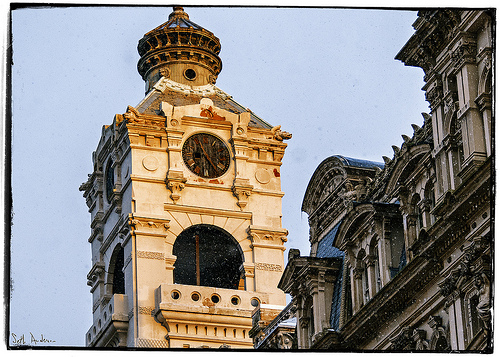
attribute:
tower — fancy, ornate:
[69, 11, 299, 345]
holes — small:
[161, 290, 262, 307]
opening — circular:
[170, 289, 180, 300]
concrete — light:
[84, 143, 292, 347]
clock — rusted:
[160, 124, 307, 206]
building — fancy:
[64, 12, 306, 355]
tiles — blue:
[314, 224, 345, 268]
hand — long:
[201, 150, 227, 174]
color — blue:
[312, 217, 345, 327]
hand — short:
[196, 136, 206, 153]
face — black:
[182, 130, 229, 178]